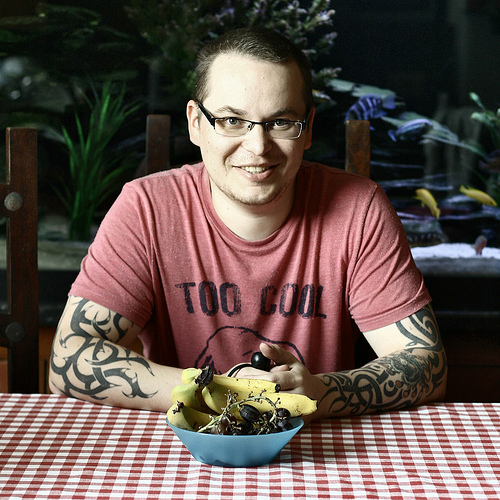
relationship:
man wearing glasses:
[47, 25, 451, 421] [194, 98, 314, 141]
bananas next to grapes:
[167, 365, 317, 429] [194, 387, 293, 436]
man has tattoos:
[47, 25, 451, 421] [319, 302, 447, 413]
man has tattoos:
[47, 25, 451, 421] [47, 293, 158, 399]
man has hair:
[47, 25, 451, 421] [188, 25, 315, 111]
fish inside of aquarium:
[343, 94, 498, 217] [1, 1, 500, 278]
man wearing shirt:
[47, 25, 451, 421] [68, 159, 434, 374]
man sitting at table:
[47, 25, 451, 421] [1, 392, 499, 498]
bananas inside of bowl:
[167, 365, 317, 429] [165, 417, 304, 468]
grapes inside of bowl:
[194, 387, 293, 436] [165, 417, 304, 468]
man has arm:
[47, 25, 451, 421] [306, 183, 450, 421]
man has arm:
[47, 25, 451, 421] [47, 185, 184, 413]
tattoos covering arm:
[319, 302, 447, 413] [306, 183, 450, 421]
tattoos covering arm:
[47, 293, 158, 399] [47, 185, 184, 413]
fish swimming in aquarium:
[343, 94, 498, 217] [1, 1, 500, 278]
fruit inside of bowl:
[168, 364, 318, 434] [165, 417, 304, 468]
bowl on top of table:
[165, 417, 304, 468] [1, 392, 499, 498]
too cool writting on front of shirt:
[174, 280, 329, 320] [68, 159, 434, 374]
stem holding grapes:
[196, 388, 281, 435] [194, 387, 293, 436]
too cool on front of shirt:
[174, 280, 329, 320] [68, 159, 434, 374]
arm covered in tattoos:
[306, 183, 450, 421] [319, 302, 447, 413]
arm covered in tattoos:
[47, 185, 184, 413] [47, 293, 158, 399]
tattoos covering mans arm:
[319, 302, 447, 413] [306, 183, 450, 421]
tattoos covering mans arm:
[47, 293, 158, 399] [47, 185, 184, 413]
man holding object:
[47, 25, 451, 421] [226, 351, 276, 377]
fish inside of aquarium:
[415, 180, 497, 218] [1, 1, 500, 278]